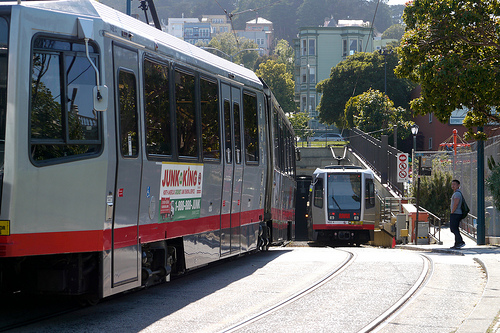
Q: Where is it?
A: This is at the road.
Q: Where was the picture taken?
A: It was taken at the road.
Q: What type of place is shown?
A: It is a road.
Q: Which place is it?
A: It is a road.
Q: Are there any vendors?
A: No, there are no vendors.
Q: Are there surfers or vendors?
A: No, there are no vendors or surfers.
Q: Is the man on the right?
A: Yes, the man is on the right of the image.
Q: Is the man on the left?
A: No, the man is on the right of the image.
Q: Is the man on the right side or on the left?
A: The man is on the right of the image.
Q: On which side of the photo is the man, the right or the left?
A: The man is on the right of the image.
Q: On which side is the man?
A: The man is on the right of the image.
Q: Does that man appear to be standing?
A: Yes, the man is standing.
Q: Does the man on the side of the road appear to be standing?
A: Yes, the man is standing.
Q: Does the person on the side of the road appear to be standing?
A: Yes, the man is standing.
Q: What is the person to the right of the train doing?
A: The man is standing.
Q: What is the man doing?
A: The man is standing.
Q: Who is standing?
A: The man is standing.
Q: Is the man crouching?
A: No, the man is standing.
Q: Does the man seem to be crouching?
A: No, the man is standing.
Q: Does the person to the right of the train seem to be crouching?
A: No, the man is standing.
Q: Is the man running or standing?
A: The man is standing.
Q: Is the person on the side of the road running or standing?
A: The man is standing.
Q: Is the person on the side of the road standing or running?
A: The man is standing.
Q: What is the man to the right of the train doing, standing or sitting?
A: The man is standing.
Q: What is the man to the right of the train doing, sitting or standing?
A: The man is standing.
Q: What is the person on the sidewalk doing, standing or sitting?
A: The man is standing.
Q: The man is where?
A: The man is on the sidewalk.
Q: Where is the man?
A: The man is on the sidewalk.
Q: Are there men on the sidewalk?
A: Yes, there is a man on the sidewalk.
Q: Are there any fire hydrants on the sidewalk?
A: No, there is a man on the sidewalk.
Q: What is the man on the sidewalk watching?
A: The man is watching the train.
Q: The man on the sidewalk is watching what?
A: The man is watching the train.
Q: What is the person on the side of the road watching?
A: The man is watching the train.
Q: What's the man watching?
A: The man is watching the train.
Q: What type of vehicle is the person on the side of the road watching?
A: The man is watching the train.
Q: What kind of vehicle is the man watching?
A: The man is watching the train.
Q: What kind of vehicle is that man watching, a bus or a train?
A: The man is watching a train.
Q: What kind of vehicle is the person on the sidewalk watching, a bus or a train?
A: The man is watching a train.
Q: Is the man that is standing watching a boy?
A: No, the man is watching the train.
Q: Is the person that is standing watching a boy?
A: No, the man is watching the train.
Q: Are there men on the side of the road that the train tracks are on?
A: Yes, there is a man on the side of the road.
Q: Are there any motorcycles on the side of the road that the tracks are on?
A: No, there is a man on the side of the road.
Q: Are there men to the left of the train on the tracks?
A: No, the man is to the right of the train.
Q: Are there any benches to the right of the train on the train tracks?
A: No, there is a man to the right of the train.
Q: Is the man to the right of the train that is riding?
A: Yes, the man is to the right of the train.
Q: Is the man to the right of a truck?
A: No, the man is to the right of the train.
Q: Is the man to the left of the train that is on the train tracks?
A: No, the man is to the right of the train.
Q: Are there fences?
A: Yes, there is a fence.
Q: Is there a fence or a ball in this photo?
A: Yes, there is a fence.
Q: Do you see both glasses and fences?
A: No, there is a fence but no glasses.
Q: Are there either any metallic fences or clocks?
A: Yes, there is a metal fence.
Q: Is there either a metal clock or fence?
A: Yes, there is a metal fence.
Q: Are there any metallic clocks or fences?
A: Yes, there is a metal fence.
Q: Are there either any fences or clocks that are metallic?
A: Yes, the fence is metallic.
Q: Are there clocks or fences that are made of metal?
A: Yes, the fence is made of metal.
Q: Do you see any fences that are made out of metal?
A: Yes, there is a fence that is made of metal.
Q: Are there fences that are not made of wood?
A: Yes, there is a fence that is made of metal.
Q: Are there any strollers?
A: No, there are no strollers.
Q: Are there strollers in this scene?
A: No, there are no strollers.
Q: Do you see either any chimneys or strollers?
A: No, there are no strollers or chimneys.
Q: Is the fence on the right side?
A: Yes, the fence is on the right of the image.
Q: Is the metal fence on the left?
A: No, the fence is on the right of the image.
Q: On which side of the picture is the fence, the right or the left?
A: The fence is on the right of the image.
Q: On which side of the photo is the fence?
A: The fence is on the right of the image.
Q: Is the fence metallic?
A: Yes, the fence is metallic.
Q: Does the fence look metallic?
A: Yes, the fence is metallic.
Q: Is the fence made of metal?
A: Yes, the fence is made of metal.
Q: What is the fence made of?
A: The fence is made of metal.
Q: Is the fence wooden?
A: No, the fence is metallic.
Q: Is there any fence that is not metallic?
A: No, there is a fence but it is metallic.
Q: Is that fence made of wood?
A: No, the fence is made of metal.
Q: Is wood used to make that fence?
A: No, the fence is made of metal.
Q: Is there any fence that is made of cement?
A: No, there is a fence but it is made of metal.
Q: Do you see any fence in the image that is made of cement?
A: No, there is a fence but it is made of metal.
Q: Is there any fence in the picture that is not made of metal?
A: No, there is a fence but it is made of metal.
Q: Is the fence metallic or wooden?
A: The fence is metallic.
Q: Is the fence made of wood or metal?
A: The fence is made of metal.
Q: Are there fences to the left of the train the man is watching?
A: No, the fence is to the right of the train.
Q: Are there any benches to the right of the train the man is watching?
A: No, there is a fence to the right of the train.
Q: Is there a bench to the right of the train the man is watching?
A: No, there is a fence to the right of the train.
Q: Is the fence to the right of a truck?
A: No, the fence is to the right of the train.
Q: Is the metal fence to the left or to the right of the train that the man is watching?
A: The fence is to the right of the train.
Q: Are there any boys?
A: No, there are no boys.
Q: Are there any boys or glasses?
A: No, there are no boys or glasses.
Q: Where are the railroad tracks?
A: The railroad tracks are on the road.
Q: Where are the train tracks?
A: The railroad tracks are on the road.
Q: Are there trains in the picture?
A: Yes, there is a train.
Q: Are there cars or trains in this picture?
A: Yes, there is a train.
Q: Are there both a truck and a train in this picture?
A: No, there is a train but no trucks.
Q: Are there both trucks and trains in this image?
A: No, there is a train but no trucks.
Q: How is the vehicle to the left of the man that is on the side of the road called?
A: The vehicle is a train.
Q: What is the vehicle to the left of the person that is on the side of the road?
A: The vehicle is a train.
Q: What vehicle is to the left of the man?
A: The vehicle is a train.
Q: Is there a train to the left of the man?
A: Yes, there is a train to the left of the man.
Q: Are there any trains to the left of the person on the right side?
A: Yes, there is a train to the left of the man.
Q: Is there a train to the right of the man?
A: No, the train is to the left of the man.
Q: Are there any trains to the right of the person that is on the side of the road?
A: No, the train is to the left of the man.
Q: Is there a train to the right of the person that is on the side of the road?
A: No, the train is to the left of the man.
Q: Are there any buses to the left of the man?
A: No, there is a train to the left of the man.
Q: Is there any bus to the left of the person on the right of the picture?
A: No, there is a train to the left of the man.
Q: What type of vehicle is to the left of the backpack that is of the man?
A: The vehicle is a train.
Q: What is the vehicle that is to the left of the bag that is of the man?
A: The vehicle is a train.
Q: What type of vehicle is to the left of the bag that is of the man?
A: The vehicle is a train.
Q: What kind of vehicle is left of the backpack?
A: The vehicle is a train.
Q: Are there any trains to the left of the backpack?
A: Yes, there is a train to the left of the backpack.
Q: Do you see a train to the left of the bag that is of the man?
A: Yes, there is a train to the left of the backpack.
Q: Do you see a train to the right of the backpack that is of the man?
A: No, the train is to the left of the backpack.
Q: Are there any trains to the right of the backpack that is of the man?
A: No, the train is to the left of the backpack.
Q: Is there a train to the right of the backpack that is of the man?
A: No, the train is to the left of the backpack.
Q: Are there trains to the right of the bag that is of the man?
A: No, the train is to the left of the backpack.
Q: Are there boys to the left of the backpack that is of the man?
A: No, there is a train to the left of the backpack.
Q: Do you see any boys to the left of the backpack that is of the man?
A: No, there is a train to the left of the backpack.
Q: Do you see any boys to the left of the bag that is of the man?
A: No, there is a train to the left of the backpack.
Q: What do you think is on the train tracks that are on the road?
A: The train is on the tracks.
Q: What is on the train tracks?
A: The train is on the tracks.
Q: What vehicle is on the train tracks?
A: The vehicle is a train.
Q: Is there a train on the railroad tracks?
A: Yes, there is a train on the railroad tracks.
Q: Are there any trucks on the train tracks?
A: No, there is a train on the train tracks.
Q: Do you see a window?
A: Yes, there are windows.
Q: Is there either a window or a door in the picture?
A: Yes, there are windows.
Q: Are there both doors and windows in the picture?
A: Yes, there are both windows and a door.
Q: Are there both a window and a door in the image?
A: Yes, there are both a window and a door.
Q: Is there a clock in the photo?
A: No, there are no clocks.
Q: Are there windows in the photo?
A: Yes, there are windows.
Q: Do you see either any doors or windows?
A: Yes, there are windows.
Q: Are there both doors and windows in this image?
A: Yes, there are both windows and doors.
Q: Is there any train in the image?
A: Yes, there is a train.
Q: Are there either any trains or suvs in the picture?
A: Yes, there is a train.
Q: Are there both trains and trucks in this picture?
A: No, there is a train but no trucks.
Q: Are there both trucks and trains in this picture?
A: No, there is a train but no trucks.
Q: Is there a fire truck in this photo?
A: No, there are no fire trucks.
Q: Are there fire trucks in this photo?
A: No, there are no fire trucks.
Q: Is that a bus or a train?
A: That is a train.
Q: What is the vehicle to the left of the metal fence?
A: The vehicle is a train.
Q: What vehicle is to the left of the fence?
A: The vehicle is a train.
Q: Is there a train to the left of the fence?
A: Yes, there is a train to the left of the fence.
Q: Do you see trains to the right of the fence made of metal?
A: No, the train is to the left of the fence.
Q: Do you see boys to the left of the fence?
A: No, there is a train to the left of the fence.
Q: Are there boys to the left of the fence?
A: No, there is a train to the left of the fence.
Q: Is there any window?
A: Yes, there are windows.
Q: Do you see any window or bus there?
A: Yes, there are windows.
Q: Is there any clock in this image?
A: No, there are no clocks.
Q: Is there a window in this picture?
A: Yes, there are windows.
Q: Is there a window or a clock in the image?
A: Yes, there are windows.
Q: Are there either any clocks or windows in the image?
A: Yes, there are windows.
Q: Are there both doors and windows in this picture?
A: Yes, there are both windows and a door.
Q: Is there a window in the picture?
A: Yes, there are windows.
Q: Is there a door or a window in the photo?
A: Yes, there are windows.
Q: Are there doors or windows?
A: Yes, there are windows.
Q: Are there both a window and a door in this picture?
A: Yes, there are both a window and a door.